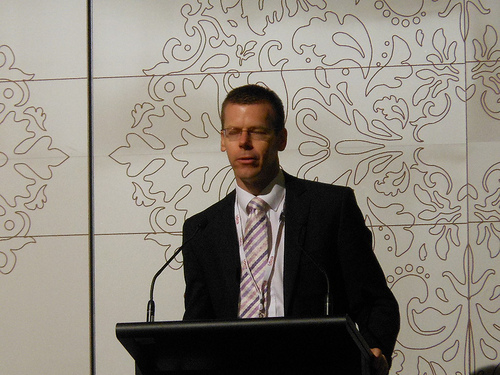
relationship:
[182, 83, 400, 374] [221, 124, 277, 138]
man wearing glasses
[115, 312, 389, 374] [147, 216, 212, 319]
podium with microphone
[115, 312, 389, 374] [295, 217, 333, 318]
podium with microphone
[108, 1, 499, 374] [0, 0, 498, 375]
artwork on wall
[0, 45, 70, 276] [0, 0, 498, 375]
artwork on wall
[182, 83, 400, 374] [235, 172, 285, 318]
man wearing shirt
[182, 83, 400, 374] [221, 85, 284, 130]
man has hair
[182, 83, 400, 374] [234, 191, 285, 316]
man wearing lanyard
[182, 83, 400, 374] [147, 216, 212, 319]
man speaking into microphone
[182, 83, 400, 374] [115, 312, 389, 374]
man at podium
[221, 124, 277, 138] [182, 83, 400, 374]
glasses on man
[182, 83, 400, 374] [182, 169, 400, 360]
man wearing jacket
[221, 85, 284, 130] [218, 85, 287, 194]
hair on head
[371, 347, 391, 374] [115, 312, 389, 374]
hand holding podium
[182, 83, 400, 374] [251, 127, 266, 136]
man with eye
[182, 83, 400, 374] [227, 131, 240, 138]
man with eye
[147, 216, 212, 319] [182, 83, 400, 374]
microphone in front of man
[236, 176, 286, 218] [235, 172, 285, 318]
neck of shirt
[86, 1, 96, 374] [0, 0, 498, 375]
separation of wall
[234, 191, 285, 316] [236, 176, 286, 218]
lanyard around neck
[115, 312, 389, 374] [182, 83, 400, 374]
podium in front of man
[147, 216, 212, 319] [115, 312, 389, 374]
microphone on podium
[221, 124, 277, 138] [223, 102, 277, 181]
glasses on face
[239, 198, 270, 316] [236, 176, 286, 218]
tie around neck